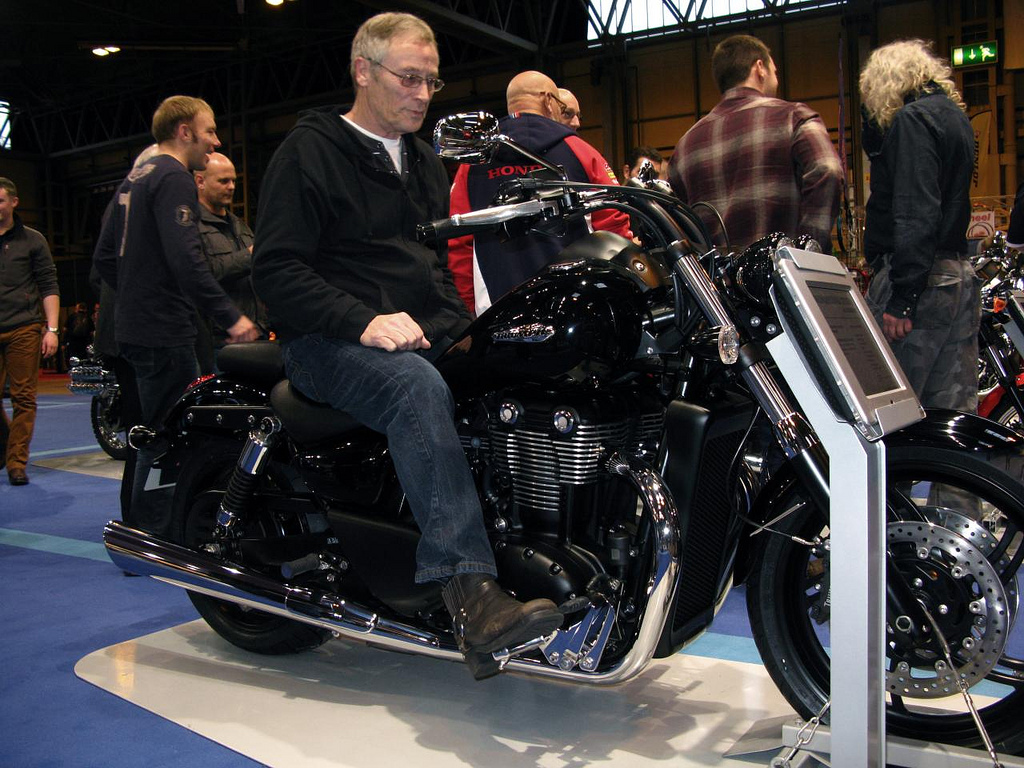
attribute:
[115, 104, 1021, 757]
motorcycle — black, shiny